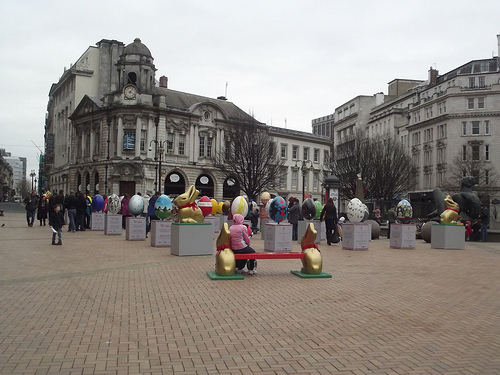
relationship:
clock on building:
[118, 81, 142, 105] [72, 37, 335, 203]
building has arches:
[72, 37, 335, 203] [163, 164, 245, 199]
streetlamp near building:
[146, 136, 176, 190] [72, 37, 335, 203]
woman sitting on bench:
[229, 214, 256, 274] [206, 247, 334, 280]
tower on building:
[112, 37, 157, 108] [72, 37, 335, 203]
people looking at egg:
[26, 187, 95, 246] [88, 189, 106, 235]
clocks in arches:
[170, 171, 242, 188] [163, 164, 245, 199]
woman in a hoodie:
[229, 214, 256, 274] [229, 215, 249, 249]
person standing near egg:
[320, 197, 345, 245] [298, 196, 322, 222]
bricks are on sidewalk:
[2, 262, 177, 293] [3, 253, 499, 374]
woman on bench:
[229, 214, 256, 274] [206, 247, 334, 280]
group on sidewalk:
[26, 187, 95, 246] [3, 253, 499, 374]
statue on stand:
[389, 199, 417, 250] [389, 223, 419, 252]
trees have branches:
[215, 116, 289, 193] [210, 156, 238, 172]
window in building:
[121, 114, 140, 158] [72, 37, 335, 203]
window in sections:
[166, 119, 190, 159] [164, 117, 333, 168]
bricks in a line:
[2, 262, 177, 293] [4, 252, 176, 286]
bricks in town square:
[2, 262, 177, 293] [12, 188, 484, 357]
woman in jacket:
[229, 214, 256, 274] [229, 215, 249, 249]